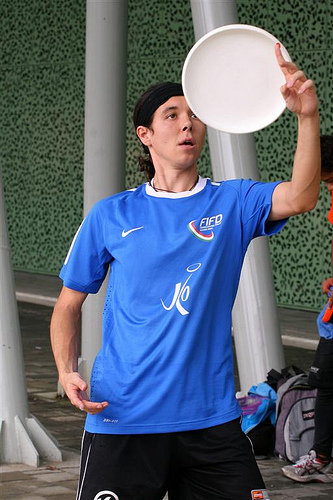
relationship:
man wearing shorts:
[48, 43, 323, 499] [77, 420, 268, 500]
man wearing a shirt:
[48, 43, 323, 499] [58, 179, 286, 436]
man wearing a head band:
[48, 43, 323, 499] [133, 84, 189, 130]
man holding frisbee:
[48, 43, 323, 499] [181, 23, 293, 137]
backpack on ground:
[277, 366, 320, 465] [5, 304, 330, 499]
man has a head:
[48, 43, 323, 499] [133, 81, 206, 169]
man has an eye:
[48, 43, 323, 499] [165, 111, 179, 121]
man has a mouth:
[48, 43, 323, 499] [179, 139, 197, 149]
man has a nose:
[48, 43, 323, 499] [183, 116, 194, 131]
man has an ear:
[48, 43, 323, 499] [135, 126, 154, 147]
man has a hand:
[48, 43, 323, 499] [275, 41, 321, 116]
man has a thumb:
[48, 43, 323, 499] [72, 377, 88, 391]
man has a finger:
[48, 43, 323, 499] [277, 42, 291, 76]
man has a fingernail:
[48, 43, 323, 499] [79, 405, 85, 411]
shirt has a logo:
[58, 179, 286, 436] [120, 224, 144, 239]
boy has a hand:
[48, 43, 323, 499] [275, 41, 321, 116]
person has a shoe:
[279, 135, 332, 485] [280, 446, 331, 483]